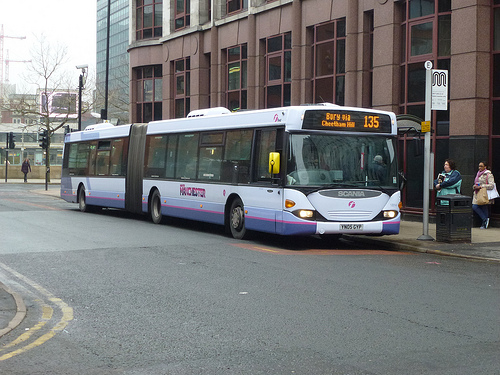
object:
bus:
[59, 103, 401, 246]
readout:
[318, 110, 384, 130]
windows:
[62, 134, 128, 177]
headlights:
[296, 208, 395, 222]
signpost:
[421, 61, 453, 242]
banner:
[431, 69, 450, 111]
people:
[436, 159, 499, 229]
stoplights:
[35, 126, 53, 189]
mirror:
[266, 150, 281, 175]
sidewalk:
[400, 217, 500, 264]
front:
[283, 103, 404, 241]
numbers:
[362, 113, 381, 129]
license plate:
[338, 223, 365, 232]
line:
[1, 262, 75, 368]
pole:
[422, 59, 432, 243]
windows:
[133, 5, 448, 130]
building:
[130, 1, 497, 221]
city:
[2, 2, 499, 372]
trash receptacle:
[433, 191, 475, 245]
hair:
[444, 156, 457, 170]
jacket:
[470, 170, 497, 207]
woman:
[19, 157, 31, 184]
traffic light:
[4, 131, 16, 183]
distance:
[0, 122, 68, 189]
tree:
[17, 45, 64, 184]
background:
[0, 1, 130, 209]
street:
[1, 183, 500, 373]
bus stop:
[420, 55, 497, 252]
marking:
[234, 239, 424, 258]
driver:
[297, 144, 329, 188]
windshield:
[284, 134, 400, 190]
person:
[432, 159, 463, 195]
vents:
[181, 103, 234, 116]